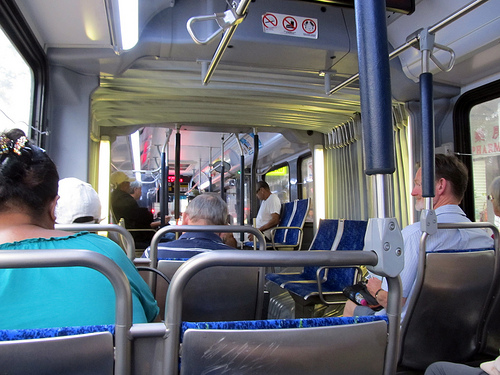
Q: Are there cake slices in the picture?
A: No, there are no cake slices.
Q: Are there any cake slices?
A: No, there are no cake slices.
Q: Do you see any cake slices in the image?
A: No, there are no cake slices.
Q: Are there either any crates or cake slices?
A: No, there are no cake slices or crates.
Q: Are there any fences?
A: No, there are no fences.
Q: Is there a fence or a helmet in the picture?
A: No, there are no fences or helmets.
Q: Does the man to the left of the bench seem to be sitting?
A: Yes, the man is sitting.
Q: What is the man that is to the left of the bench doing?
A: The man is sitting.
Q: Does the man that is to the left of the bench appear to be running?
A: No, the man is sitting.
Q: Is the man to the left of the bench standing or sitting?
A: The man is sitting.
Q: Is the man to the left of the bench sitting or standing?
A: The man is sitting.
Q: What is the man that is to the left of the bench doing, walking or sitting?
A: The man is sitting.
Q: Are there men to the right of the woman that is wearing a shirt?
A: Yes, there is a man to the right of the woman.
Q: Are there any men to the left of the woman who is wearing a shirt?
A: No, the man is to the right of the woman.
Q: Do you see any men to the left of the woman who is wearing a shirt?
A: No, the man is to the right of the woman.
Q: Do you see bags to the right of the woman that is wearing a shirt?
A: No, there is a man to the right of the woman.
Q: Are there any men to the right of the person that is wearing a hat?
A: Yes, there is a man to the right of the person.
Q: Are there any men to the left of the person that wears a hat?
A: No, the man is to the right of the person.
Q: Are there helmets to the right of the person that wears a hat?
A: No, there is a man to the right of the person.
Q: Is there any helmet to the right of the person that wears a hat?
A: No, there is a man to the right of the person.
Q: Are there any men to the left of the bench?
A: Yes, there is a man to the left of the bench.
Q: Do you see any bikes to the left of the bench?
A: No, there is a man to the left of the bench.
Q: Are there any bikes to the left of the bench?
A: No, there is a man to the left of the bench.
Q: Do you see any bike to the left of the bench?
A: No, there is a man to the left of the bench.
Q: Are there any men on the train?
A: Yes, there is a man on the train.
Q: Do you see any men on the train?
A: Yes, there is a man on the train.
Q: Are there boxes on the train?
A: No, there is a man on the train.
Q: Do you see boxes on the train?
A: No, there is a man on the train.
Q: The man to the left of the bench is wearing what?
A: The man is wearing a shirt.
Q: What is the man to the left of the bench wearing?
A: The man is wearing a shirt.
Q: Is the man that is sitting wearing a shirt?
A: Yes, the man is wearing a shirt.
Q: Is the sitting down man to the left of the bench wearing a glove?
A: No, the man is wearing a shirt.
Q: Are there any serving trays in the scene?
A: No, there are no serving trays.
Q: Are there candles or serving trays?
A: No, there are no serving trays or candles.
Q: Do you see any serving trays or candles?
A: No, there are no serving trays or candles.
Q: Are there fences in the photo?
A: No, there are no fences.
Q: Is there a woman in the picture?
A: Yes, there is a woman.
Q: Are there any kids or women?
A: Yes, there is a woman.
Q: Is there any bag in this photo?
A: No, there are no bags.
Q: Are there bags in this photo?
A: No, there are no bags.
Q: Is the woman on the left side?
A: Yes, the woman is on the left of the image.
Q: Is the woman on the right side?
A: No, the woman is on the left of the image.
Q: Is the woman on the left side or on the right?
A: The woman is on the left of the image.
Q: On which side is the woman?
A: The woman is on the left of the image.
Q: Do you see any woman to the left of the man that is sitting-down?
A: Yes, there is a woman to the left of the man.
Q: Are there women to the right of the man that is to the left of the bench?
A: No, the woman is to the left of the man.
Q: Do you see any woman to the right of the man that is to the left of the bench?
A: No, the woman is to the left of the man.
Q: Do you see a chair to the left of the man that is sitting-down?
A: No, there is a woman to the left of the man.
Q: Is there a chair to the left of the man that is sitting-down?
A: No, there is a woman to the left of the man.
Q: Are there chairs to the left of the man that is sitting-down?
A: No, there is a woman to the left of the man.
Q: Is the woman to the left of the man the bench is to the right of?
A: Yes, the woman is to the left of the man.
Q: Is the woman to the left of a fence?
A: No, the woman is to the left of the man.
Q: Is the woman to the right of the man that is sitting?
A: No, the woman is to the left of the man.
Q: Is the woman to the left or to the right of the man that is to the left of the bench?
A: The woman is to the left of the man.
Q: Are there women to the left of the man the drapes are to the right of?
A: Yes, there is a woman to the left of the man.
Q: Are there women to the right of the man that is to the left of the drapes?
A: No, the woman is to the left of the man.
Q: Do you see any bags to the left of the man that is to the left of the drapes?
A: No, there is a woman to the left of the man.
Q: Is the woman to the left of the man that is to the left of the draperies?
A: Yes, the woman is to the left of the man.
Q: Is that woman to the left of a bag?
A: No, the woman is to the left of the man.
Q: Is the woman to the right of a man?
A: No, the woman is to the left of a man.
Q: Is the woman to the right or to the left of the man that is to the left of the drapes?
A: The woman is to the left of the man.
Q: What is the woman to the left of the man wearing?
A: The woman is wearing a shirt.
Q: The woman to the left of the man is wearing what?
A: The woman is wearing a shirt.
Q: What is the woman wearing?
A: The woman is wearing a shirt.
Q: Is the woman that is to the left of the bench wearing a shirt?
A: Yes, the woman is wearing a shirt.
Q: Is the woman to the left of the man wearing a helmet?
A: No, the woman is wearing a shirt.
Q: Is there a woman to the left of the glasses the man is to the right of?
A: Yes, there is a woman to the left of the glasses.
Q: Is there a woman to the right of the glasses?
A: No, the woman is to the left of the glasses.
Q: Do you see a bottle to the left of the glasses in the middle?
A: No, there is a woman to the left of the glasses.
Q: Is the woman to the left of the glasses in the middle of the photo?
A: Yes, the woman is to the left of the glasses.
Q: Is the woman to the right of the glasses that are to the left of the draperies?
A: No, the woman is to the left of the glasses.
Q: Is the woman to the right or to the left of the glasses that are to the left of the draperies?
A: The woman is to the left of the glasses.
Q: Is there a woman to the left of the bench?
A: Yes, there is a woman to the left of the bench.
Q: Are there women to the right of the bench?
A: No, the woman is to the left of the bench.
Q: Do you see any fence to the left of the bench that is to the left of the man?
A: No, there is a woman to the left of the bench.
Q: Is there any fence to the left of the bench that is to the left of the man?
A: No, there is a woman to the left of the bench.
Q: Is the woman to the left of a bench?
A: Yes, the woman is to the left of a bench.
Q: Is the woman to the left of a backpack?
A: No, the woman is to the left of a bench.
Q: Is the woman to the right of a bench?
A: No, the woman is to the left of a bench.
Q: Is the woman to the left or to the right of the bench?
A: The woman is to the left of the bench.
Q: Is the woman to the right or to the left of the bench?
A: The woman is to the left of the bench.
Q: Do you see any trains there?
A: Yes, there is a train.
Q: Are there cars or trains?
A: Yes, there is a train.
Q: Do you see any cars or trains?
A: Yes, there is a train.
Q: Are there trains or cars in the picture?
A: Yes, there is a train.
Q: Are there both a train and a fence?
A: No, there is a train but no fences.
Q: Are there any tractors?
A: No, there are no tractors.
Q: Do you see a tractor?
A: No, there are no tractors.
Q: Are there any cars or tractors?
A: No, there are no tractors or cars.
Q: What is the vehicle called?
A: The vehicle is a train.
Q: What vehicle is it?
A: The vehicle is a train.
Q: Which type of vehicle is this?
A: This is a train.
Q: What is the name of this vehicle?
A: This is a train.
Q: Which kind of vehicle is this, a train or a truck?
A: This is a train.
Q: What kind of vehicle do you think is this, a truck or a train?
A: This is a train.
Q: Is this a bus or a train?
A: This is a train.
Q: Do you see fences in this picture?
A: No, there are no fences.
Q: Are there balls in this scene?
A: No, there are no balls.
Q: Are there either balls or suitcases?
A: No, there are no balls or suitcases.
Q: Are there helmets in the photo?
A: No, there are no helmets.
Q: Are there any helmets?
A: No, there are no helmets.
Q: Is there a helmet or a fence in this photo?
A: No, there are no helmets or fences.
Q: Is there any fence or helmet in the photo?
A: No, there are no helmets or fences.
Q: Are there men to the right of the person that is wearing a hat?
A: Yes, there is a man to the right of the person.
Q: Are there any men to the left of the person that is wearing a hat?
A: No, the man is to the right of the person.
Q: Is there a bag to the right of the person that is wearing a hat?
A: No, there is a man to the right of the person.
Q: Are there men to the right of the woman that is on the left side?
A: Yes, there is a man to the right of the woman.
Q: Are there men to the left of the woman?
A: No, the man is to the right of the woman.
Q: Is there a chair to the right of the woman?
A: No, there is a man to the right of the woman.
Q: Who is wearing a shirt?
A: The man is wearing a shirt.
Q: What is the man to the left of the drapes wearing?
A: The man is wearing a shirt.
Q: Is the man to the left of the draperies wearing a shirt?
A: Yes, the man is wearing a shirt.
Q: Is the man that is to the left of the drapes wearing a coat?
A: No, the man is wearing a shirt.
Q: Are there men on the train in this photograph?
A: Yes, there is a man on the train.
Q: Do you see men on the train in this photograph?
A: Yes, there is a man on the train.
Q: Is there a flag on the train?
A: No, there is a man on the train.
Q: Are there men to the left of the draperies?
A: Yes, there is a man to the left of the draperies.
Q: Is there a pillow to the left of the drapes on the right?
A: No, there is a man to the left of the draperies.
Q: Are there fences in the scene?
A: No, there are no fences.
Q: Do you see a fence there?
A: No, there are no fences.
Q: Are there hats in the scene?
A: Yes, there is a hat.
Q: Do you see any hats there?
A: Yes, there is a hat.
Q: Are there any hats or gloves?
A: Yes, there is a hat.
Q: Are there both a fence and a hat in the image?
A: No, there is a hat but no fences.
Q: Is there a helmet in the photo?
A: No, there are no helmets.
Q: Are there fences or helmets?
A: No, there are no helmets or fences.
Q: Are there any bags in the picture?
A: No, there are no bags.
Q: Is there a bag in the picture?
A: No, there are no bags.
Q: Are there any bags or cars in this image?
A: No, there are no bags or cars.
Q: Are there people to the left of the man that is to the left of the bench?
A: Yes, there is a person to the left of the man.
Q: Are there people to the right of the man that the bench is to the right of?
A: No, the person is to the left of the man.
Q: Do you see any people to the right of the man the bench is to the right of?
A: No, the person is to the left of the man.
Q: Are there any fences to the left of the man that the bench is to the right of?
A: No, there is a person to the left of the man.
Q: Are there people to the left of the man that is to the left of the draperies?
A: Yes, there is a person to the left of the man.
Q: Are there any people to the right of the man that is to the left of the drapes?
A: No, the person is to the left of the man.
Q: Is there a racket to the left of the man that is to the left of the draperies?
A: No, there is a person to the left of the man.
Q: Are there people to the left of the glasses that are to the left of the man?
A: Yes, there is a person to the left of the glasses.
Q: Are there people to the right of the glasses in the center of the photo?
A: No, the person is to the left of the glasses.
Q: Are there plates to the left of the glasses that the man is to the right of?
A: No, there is a person to the left of the glasses.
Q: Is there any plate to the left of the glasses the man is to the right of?
A: No, there is a person to the left of the glasses.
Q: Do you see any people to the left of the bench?
A: Yes, there is a person to the left of the bench.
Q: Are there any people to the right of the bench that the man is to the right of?
A: No, the person is to the left of the bench.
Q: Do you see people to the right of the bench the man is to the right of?
A: No, the person is to the left of the bench.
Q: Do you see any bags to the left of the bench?
A: No, there is a person to the left of the bench.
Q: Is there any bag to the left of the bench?
A: No, there is a person to the left of the bench.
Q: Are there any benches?
A: Yes, there is a bench.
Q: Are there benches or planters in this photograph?
A: Yes, there is a bench.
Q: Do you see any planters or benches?
A: Yes, there is a bench.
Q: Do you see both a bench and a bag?
A: No, there is a bench but no bags.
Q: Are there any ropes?
A: No, there are no ropes.